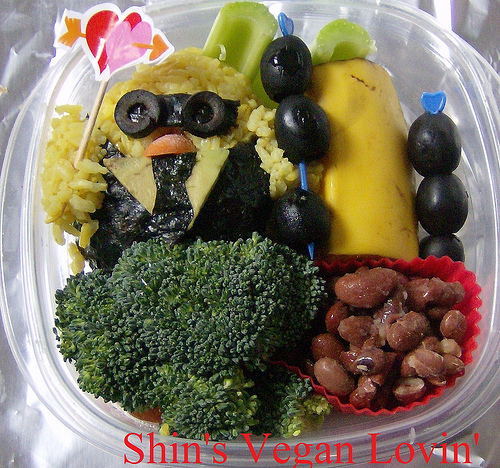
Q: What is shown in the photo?
A: Food.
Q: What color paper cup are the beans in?
A: Red.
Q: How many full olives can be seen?
A: Six.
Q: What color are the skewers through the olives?
A: Blue.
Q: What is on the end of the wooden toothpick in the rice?
A: Hearts.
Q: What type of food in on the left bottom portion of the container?
A: Broccoli.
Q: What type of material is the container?
A: Plastic.